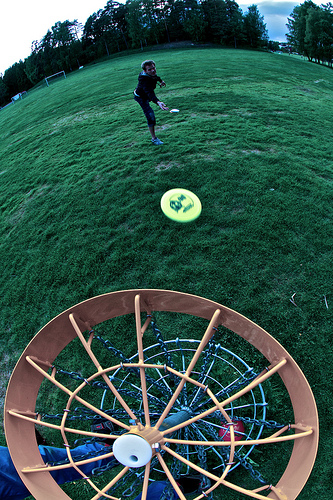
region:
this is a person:
[113, 47, 182, 151]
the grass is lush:
[54, 208, 103, 258]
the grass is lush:
[21, 274, 52, 308]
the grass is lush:
[274, 230, 323, 313]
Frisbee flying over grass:
[154, 184, 205, 226]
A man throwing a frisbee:
[132, 60, 181, 146]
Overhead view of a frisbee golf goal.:
[4, 287, 329, 499]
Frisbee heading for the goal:
[4, 188, 329, 493]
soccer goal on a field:
[40, 70, 71, 88]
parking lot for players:
[274, 46, 302, 58]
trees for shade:
[85, 1, 273, 56]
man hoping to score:
[129, 58, 185, 146]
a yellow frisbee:
[159, 184, 203, 223]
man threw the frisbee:
[111, 42, 210, 248]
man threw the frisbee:
[126, 46, 201, 234]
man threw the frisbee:
[122, 41, 210, 250]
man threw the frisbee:
[131, 54, 204, 233]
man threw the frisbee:
[124, 52, 219, 241]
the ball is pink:
[214, 417, 247, 446]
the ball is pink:
[210, 407, 242, 440]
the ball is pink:
[218, 421, 250, 442]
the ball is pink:
[214, 410, 252, 448]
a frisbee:
[159, 190, 210, 220]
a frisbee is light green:
[159, 184, 207, 223]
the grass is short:
[260, 192, 300, 241]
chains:
[151, 332, 173, 360]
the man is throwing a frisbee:
[130, 53, 187, 150]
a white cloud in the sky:
[264, 5, 286, 33]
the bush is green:
[212, 12, 239, 38]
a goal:
[39, 72, 72, 84]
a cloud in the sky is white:
[264, 4, 285, 33]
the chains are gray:
[216, 411, 279, 431]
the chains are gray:
[201, 421, 253, 482]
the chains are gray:
[181, 428, 220, 497]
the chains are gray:
[204, 426, 264, 496]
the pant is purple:
[1, 431, 121, 498]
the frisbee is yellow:
[149, 180, 207, 235]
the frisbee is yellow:
[151, 173, 208, 234]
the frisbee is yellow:
[147, 177, 211, 235]